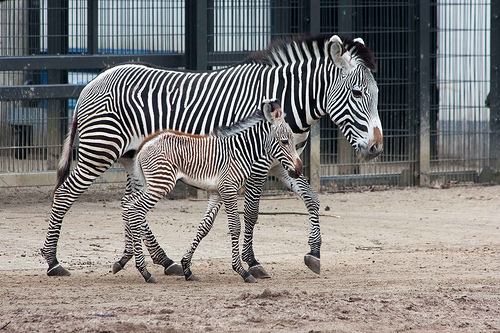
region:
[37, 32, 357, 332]
a zebraand a young one walikng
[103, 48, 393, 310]
zebras are walking in same direction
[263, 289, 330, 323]
the floor is coverd of soil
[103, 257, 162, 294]
the hoofs are black in color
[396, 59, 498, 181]
the fence is made of wires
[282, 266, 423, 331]
floor is brown in colro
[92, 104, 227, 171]
the zebra is black and white stripped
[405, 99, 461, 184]
the posts are wooden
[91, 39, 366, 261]
they are walking past the fence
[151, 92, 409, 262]
walking in tha same directuion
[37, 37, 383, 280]
Zebras walking in a pen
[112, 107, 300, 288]
A baby zebra with its mother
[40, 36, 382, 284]
A mother zebra with its baby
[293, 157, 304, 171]
Small baby zebra nose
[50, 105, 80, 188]
Black and white tail on a zebra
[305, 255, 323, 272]
A hoof on a zebra's front foot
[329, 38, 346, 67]
Fuzzy ear on a zebra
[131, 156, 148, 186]
Short white baby zebra tail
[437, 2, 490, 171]
Wire fencing on an enclosure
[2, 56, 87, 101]
Horizontal bars on a fence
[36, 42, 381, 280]
two zebras walking together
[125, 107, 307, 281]
baby zebra with black stripes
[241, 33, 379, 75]
black and white mane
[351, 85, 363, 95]
almond shaped eye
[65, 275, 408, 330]
rough dirt ground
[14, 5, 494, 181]
metal cage with thin posts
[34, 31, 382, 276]
a mother and its baby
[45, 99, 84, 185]
short tail with long fur on the end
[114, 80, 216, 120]
white and black stripes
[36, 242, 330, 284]
two sets of hooves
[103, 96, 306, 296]
this is a baby zebra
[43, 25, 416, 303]
this is an adult zebra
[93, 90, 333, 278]
this is a zebra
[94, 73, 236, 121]
black stripes on zebra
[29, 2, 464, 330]
zebras walking on dirt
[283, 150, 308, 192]
brown nose on zebra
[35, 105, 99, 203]
hair on zebra tail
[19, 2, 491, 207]
a closure behind the zebras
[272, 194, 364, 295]
zebra leg is up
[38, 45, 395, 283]
a mother zebra with a baby zebra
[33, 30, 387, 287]
a couple of zebra are walking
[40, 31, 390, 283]
two zebras in a pen at a zoo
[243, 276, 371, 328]
disturbed sandy ground beneath zebra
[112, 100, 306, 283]
baby zebra walking near mother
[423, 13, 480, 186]
wire fencing enclosing zebra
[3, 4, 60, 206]
metal wired enclosure at a zoo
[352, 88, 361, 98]
left eye of adult zebra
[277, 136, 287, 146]
left eye of baby zebra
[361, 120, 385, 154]
nose of zebra has a brown marking on it